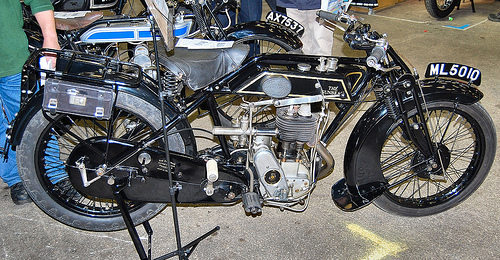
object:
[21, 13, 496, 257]
motorcycle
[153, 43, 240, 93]
seat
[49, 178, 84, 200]
boot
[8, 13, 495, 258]
concrete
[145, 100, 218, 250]
edge of a stand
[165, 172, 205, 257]
stand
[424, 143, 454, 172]
wheel cap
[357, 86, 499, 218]
back of a wheel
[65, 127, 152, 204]
an engine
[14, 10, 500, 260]
fashioned motorcyle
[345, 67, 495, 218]
front tire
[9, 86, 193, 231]
back tire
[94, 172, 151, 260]
kickstand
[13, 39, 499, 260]
motorcycle is black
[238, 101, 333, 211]
engine in motorcycle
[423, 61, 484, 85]
license plate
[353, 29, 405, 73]
handlebars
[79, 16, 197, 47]
seat on motorcycle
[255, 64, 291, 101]
gas tank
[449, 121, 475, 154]
spoke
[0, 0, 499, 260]
parking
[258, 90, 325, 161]
part of an engine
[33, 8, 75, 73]
part of an arm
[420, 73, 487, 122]
edge of a wheel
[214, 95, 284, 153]
part of the engine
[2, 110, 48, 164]
edge of an engine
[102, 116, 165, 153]
edge of a rail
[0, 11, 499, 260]
motorcycle on displa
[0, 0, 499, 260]
parked on concrete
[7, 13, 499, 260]
an antique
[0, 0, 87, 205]
collector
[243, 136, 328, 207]
has a motor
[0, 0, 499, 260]
at a show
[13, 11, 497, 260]
collection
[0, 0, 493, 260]
museum